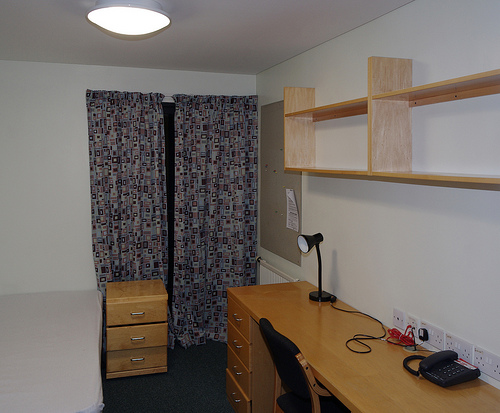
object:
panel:
[85, 88, 173, 348]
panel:
[169, 93, 262, 349]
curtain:
[172, 93, 259, 348]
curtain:
[85, 89, 174, 349]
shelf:
[285, 94, 367, 117]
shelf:
[372, 68, 500, 101]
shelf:
[284, 166, 368, 178]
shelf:
[369, 170, 499, 186]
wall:
[257, 0, 499, 391]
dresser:
[104, 279, 170, 380]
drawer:
[106, 298, 169, 326]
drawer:
[106, 322, 169, 352]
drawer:
[106, 346, 169, 374]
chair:
[257, 317, 350, 413]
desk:
[225, 280, 500, 413]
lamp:
[296, 232, 332, 302]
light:
[86, 0, 173, 36]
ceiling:
[2, 1, 415, 74]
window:
[162, 102, 175, 311]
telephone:
[403, 350, 482, 387]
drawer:
[226, 292, 254, 345]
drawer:
[227, 318, 253, 374]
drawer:
[226, 344, 254, 402]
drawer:
[224, 368, 251, 412]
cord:
[329, 303, 425, 355]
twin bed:
[1, 289, 103, 413]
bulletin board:
[258, 99, 303, 268]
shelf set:
[282, 56, 499, 190]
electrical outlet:
[473, 346, 500, 381]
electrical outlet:
[445, 330, 473, 366]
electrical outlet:
[421, 319, 444, 353]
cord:
[387, 324, 417, 346]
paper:
[285, 188, 300, 233]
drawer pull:
[131, 311, 143, 316]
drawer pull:
[131, 336, 145, 342]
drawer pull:
[130, 357, 143, 362]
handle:
[232, 313, 240, 322]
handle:
[231, 339, 241, 349]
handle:
[231, 365, 243, 376]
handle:
[230, 392, 242, 403]